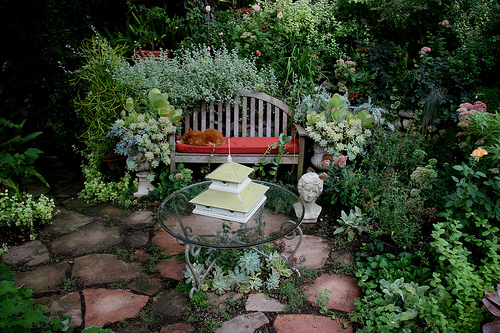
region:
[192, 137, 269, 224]
a bird house on a low table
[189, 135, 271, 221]
a bird house on a glass table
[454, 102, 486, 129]
a plant with a purple hue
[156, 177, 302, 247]
a glass table with a bird house on it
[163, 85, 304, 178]
a wooden bench with red cushion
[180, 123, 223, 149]
an animal laying on a cushion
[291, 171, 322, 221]
a replica of a female bust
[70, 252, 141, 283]
flat stone used as walkway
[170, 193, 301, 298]
metal legs of the glass table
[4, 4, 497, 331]
a garden overflowing with foliage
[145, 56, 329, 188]
wooden bench in garden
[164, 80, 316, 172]
bear in wooden bench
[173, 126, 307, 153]
red cushion on bench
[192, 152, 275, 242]
small house on glass table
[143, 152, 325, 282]
glass table in front of bench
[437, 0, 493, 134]
green vegetation in garden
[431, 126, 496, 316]
green vegetation in garden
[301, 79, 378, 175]
green vegetation in garden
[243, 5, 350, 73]
green vegetation in garden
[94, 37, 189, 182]
green vegetation in garden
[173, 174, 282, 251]
A table in the photo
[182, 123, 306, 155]
A pillow in the photo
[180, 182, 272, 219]
A book in the photo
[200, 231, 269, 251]
A glass table in the photo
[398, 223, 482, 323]
Flowers in the photo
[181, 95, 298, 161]
A bench in the photo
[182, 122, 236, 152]
A cat in the photo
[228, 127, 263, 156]
A red pillow on the bench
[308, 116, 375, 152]
White flowers in the photo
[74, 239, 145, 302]
Rocks in the photo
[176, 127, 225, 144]
the animal lying on the bench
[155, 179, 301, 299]
the glass table in the garden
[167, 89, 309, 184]
the wooden bench in the garden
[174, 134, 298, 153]
the cushion on the wooden bench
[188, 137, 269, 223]
the decoration on the table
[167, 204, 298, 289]
the greenery under the glass table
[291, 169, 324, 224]
the head and chest statue on the ground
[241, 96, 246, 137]
the wooden slat on the bench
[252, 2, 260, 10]
the flower on the bush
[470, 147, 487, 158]
the flower on the bush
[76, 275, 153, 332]
rock stuck into the ground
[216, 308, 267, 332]
rock stuck into the ground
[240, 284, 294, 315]
rock stuck into the ground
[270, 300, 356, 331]
rock stuck into the ground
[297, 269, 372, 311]
rock stuck into the ground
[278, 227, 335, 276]
rock stuck into the ground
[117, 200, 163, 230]
rock stuck into the ground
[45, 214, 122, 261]
rock stuck into the ground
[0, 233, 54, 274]
rock stuck into the ground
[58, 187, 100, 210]
rock stuck into the ground